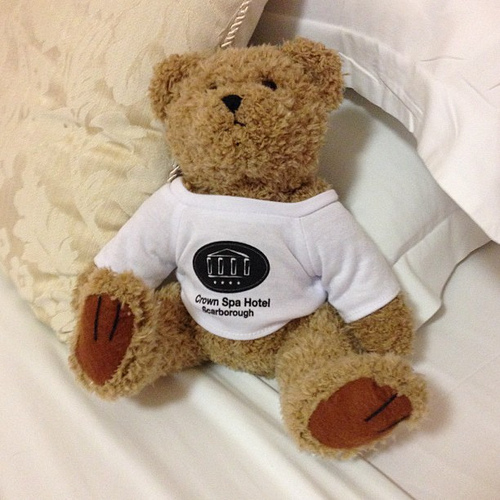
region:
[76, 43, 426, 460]
teddy bear wearing white shirt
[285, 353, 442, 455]
tan teddy bear foot with dark brown sole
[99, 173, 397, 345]
teddy bear t-shirt with logo and company naem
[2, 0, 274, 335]
rectangular tan pillow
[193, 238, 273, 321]
black and white logo Crown Spa Hotel Scarborough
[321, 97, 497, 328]
bed pillow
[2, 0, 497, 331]
pillows on bed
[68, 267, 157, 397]
teddy bear foot with toes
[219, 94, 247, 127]
sewn teddy bear nose and mouth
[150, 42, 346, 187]
teddy bear head with black nose and mouth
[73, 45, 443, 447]
the doll is brown in colour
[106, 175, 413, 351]
it has a white vest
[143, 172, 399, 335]
the vest has a black picture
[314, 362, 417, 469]
the paddings are brown in colour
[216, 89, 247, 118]
the nose is black in colour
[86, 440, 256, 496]
the sheet is white in colouor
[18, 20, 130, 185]
the pillow is white in colour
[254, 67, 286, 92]
the eyes are black in colour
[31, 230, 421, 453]
the legs are apart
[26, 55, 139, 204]
the pillow has flower patterns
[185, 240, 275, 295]
black and white logo on shirt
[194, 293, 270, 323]
black lettering on white shirt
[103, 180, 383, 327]
white shirt bear is wearing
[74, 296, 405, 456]
brown bottoms of bear's feet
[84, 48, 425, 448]
teddy bear sitting on the bed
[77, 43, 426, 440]
light brown teddy bear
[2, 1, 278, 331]
decorative throw pillow on the bed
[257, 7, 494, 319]
two pillows stacked on the bed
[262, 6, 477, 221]
shadows on the pillows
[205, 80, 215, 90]
black eye on teddy bear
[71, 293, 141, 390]
teddy bear has brown soles of feet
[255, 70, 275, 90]
black eye on teddy bear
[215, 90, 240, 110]
black nose on teddy bear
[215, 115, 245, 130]
black mouth on teddy bear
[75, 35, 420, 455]
teddybear is brown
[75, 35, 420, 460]
teddy bear is wearing white shirt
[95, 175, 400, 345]
white shirt has black logo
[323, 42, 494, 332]
white pillow under teddybear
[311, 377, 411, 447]
teddy bear has brown soles of feet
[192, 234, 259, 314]
This teddy bear has a graphic on his shirt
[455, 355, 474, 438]
There is a white sheet here that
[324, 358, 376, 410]
There is a bear that is light brown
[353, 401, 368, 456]
The bear has dark brown feet on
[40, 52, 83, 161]
The pillow is a very deep cream color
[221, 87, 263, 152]
This teddy bear has a dark black nose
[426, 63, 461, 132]
There is a white pillow that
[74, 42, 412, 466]
Jackson Mingus took this photo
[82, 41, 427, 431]
This photo was taken in Dayton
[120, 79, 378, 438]
This photo was taken in Ohio